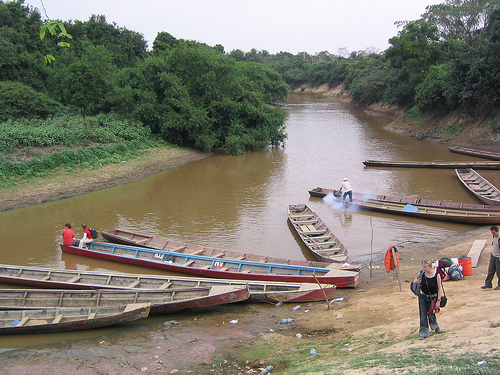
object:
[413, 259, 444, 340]
woman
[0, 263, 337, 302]
canoes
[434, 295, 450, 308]
purse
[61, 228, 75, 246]
shirt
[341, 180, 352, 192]
shirt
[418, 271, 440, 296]
top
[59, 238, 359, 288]
canoe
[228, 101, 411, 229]
water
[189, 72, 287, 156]
trees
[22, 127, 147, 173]
bushes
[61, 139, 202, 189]
shore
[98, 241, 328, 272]
railing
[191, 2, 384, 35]
sky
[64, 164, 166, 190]
dirt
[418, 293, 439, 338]
pants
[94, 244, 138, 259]
frame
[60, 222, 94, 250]
people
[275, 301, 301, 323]
bottles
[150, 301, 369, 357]
shore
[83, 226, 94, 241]
shirt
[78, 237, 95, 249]
pants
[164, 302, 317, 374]
trash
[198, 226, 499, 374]
ground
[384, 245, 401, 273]
jacket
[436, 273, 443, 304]
sleeves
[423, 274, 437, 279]
collar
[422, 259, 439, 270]
hair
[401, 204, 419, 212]
shopping bag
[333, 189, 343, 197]
engine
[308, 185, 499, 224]
boat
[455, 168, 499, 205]
boat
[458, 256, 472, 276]
bucket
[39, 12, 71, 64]
leaves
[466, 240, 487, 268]
wooden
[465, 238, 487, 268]
sidewalk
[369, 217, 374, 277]
stake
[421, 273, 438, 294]
tank top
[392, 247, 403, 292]
pole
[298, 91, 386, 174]
river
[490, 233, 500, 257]
shirt